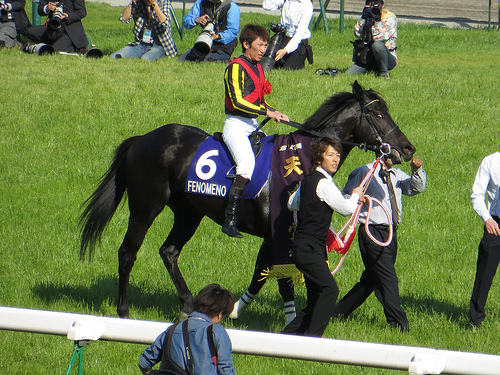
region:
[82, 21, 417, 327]
A jockey on a horse.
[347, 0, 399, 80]
A person taking a photo.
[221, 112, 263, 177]
The jockey's white pants.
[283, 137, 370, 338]
A person walking with the horse.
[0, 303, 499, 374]
A white rail in the foreground.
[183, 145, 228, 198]
The horse's number in the race.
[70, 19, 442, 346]
a black racing horse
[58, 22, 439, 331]
a black race horse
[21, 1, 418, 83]
people taking pictures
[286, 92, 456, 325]
people leading a horse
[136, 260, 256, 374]
man in a blue shirt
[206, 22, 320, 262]
a male horse jockey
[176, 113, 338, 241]
the number of the horse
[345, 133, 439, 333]
man in a suit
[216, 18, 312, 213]
jockey in white pants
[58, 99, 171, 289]
a long horses tail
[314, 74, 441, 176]
head of the horse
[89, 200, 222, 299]
back legs of horse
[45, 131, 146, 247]
tail of the horse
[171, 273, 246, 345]
head of the lady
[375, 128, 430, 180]
nose of the horse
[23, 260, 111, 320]
shadow on the ground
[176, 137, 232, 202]
number on side of horse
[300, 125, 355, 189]
head of a man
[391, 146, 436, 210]
arm of a man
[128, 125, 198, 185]
black fur on horse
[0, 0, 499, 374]
a field of green grass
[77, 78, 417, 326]
a black horse in the grass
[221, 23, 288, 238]
a rider on the horse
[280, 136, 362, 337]
a man guiding the horse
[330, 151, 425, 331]
a man guiding the horse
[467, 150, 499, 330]
a man standing in the field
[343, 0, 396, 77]
a photographer in the field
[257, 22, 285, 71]
a camera with a large lens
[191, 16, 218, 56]
a camera with a large lens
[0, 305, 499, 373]
a large white metal railing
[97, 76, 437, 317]
the horse is black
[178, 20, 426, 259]
man riding the horse